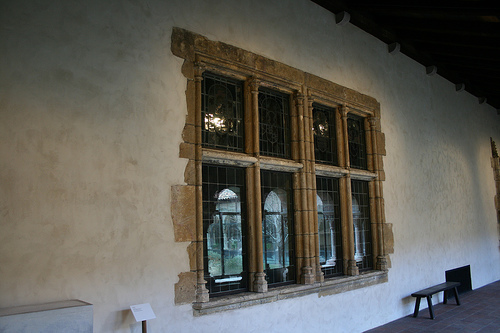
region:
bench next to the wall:
[407, 277, 466, 322]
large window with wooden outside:
[182, 40, 384, 298]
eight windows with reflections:
[185, 44, 388, 304]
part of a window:
[190, 146, 252, 315]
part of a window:
[304, 88, 344, 178]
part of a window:
[196, 60, 256, 157]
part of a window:
[256, 161, 308, 301]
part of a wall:
[43, 99, 198, 196]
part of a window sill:
[192, 275, 277, 311]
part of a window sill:
[316, 258, 386, 283]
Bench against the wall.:
[400, 268, 465, 315]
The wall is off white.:
[31, 42, 192, 313]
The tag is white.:
[129, 297, 161, 327]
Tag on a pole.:
[121, 300, 163, 332]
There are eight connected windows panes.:
[169, 53, 396, 296]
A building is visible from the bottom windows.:
[216, 190, 369, 265]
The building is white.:
[208, 185, 363, 258]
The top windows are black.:
[186, 63, 383, 179]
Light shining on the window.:
[197, 88, 246, 143]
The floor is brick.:
[386, 271, 498, 331]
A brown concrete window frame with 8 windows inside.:
[171, 27, 391, 312]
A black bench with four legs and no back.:
[409, 279, 461, 320]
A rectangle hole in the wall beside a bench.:
[443, 263, 475, 295]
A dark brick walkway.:
[373, 282, 499, 332]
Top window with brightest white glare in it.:
[196, 61, 246, 152]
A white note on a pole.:
[129, 302, 156, 324]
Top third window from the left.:
[309, 101, 341, 163]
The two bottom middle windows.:
[260, 167, 347, 291]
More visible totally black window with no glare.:
[257, 87, 296, 160]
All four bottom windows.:
[201, 159, 377, 296]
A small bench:
[403, 263, 468, 323]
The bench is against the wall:
[403, 258, 469, 319]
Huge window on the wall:
[161, 37, 424, 291]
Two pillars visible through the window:
[323, 194, 382, 271]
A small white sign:
[124, 298, 166, 325]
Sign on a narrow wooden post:
[128, 288, 161, 330]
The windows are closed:
[203, 94, 376, 277]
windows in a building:
[166, 25, 393, 293]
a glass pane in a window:
[260, 169, 301, 281]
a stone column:
[325, 220, 336, 264]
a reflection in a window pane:
[207, 178, 252, 278]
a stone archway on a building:
[264, 183, 296, 223]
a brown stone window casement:
[167, 19, 392, 303]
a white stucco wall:
[415, 131, 475, 226]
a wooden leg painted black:
[427, 300, 437, 320]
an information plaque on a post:
[127, 299, 159, 331]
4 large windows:
[149, 56, 404, 317]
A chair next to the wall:
[378, 262, 462, 314]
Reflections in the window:
[186, 185, 357, 285]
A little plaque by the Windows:
[115, 243, 187, 324]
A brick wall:
[2, 78, 147, 168]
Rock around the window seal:
[133, 40, 323, 275]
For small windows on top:
[153, 70, 398, 162]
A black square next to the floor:
[429, 246, 486, 293]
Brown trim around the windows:
[296, 99, 407, 280]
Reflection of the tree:
[225, 179, 316, 279]